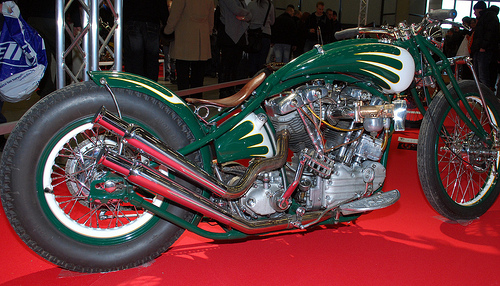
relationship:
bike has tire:
[0, 9, 500, 274] [415, 80, 500, 223]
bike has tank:
[0, 9, 500, 274] [255, 28, 415, 98]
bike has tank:
[0, 9, 500, 274] [239, 37, 418, 118]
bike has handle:
[0, 9, 500, 274] [396, 5, 478, 36]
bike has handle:
[0, 9, 500, 274] [334, 25, 371, 38]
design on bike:
[356, 42, 412, 92] [64, 34, 426, 244]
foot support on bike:
[342, 186, 398, 215] [0, 10, 497, 272]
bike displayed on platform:
[0, 9, 500, 274] [0, 49, 500, 286]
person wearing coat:
[161, 0, 221, 92] [164, 0, 217, 60]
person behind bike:
[161, 0, 221, 92] [22, 33, 499, 223]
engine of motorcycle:
[267, 85, 343, 144] [13, 9, 495, 256]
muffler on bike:
[94, 105, 331, 235] [0, 9, 500, 274]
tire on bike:
[1, 82, 205, 270] [0, 9, 500, 274]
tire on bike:
[411, 75, 498, 223] [0, 9, 500, 274]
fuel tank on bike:
[266, 24, 413, 106] [0, 9, 500, 274]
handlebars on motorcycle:
[329, 4, 453, 45] [29, 9, 486, 274]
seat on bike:
[185, 71, 266, 108] [0, 9, 500, 274]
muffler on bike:
[94, 105, 288, 199] [0, 9, 500, 274]